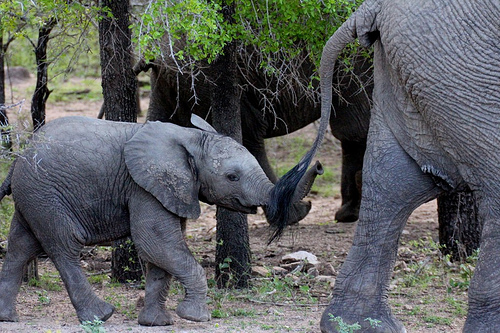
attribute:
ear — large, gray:
[120, 118, 201, 221]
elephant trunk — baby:
[245, 150, 341, 223]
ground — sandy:
[19, 77, 493, 307]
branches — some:
[201, 43, 301, 120]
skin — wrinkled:
[308, 1, 498, 331]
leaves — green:
[140, 9, 292, 81]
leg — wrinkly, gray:
[320, 129, 430, 329]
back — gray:
[22, 121, 149, 174]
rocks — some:
[276, 249, 329, 299]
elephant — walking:
[10, 59, 317, 331]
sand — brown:
[247, 312, 305, 328]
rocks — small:
[253, 244, 333, 289]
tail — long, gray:
[265, 3, 380, 257]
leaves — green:
[170, 14, 327, 69]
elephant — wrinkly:
[294, 25, 499, 330]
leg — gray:
[320, 106, 427, 331]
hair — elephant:
[272, 154, 304, 229]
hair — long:
[258, 147, 332, 247]